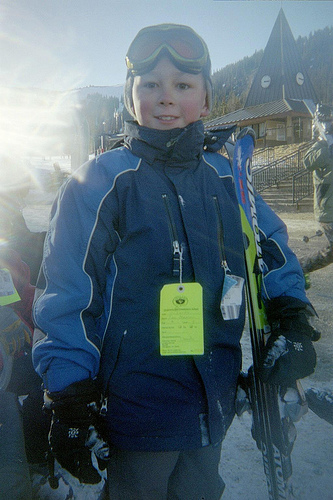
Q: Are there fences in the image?
A: No, there are no fences.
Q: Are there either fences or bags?
A: No, there are no fences or bags.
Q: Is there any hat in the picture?
A: Yes, there is a hat.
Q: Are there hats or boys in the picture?
A: Yes, there is a hat.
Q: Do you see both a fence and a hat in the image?
A: No, there is a hat but no fences.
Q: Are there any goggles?
A: Yes, there are goggles.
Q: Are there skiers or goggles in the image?
A: Yes, there are goggles.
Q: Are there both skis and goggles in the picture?
A: Yes, there are both goggles and a ski.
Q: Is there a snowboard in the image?
A: No, there are no snowboards.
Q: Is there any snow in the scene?
A: Yes, there is snow.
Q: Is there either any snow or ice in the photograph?
A: Yes, there is snow.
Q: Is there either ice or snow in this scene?
A: Yes, there is snow.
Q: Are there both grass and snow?
A: No, there is snow but no grass.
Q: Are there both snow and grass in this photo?
A: No, there is snow but no grass.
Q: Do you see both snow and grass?
A: No, there is snow but no grass.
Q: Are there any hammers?
A: No, there are no hammers.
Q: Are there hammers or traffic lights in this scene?
A: No, there are no hammers or traffic lights.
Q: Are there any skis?
A: Yes, there are skis.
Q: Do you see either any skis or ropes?
A: Yes, there are skis.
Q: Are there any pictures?
A: No, there are no pictures.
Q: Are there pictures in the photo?
A: No, there are no pictures.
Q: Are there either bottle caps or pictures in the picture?
A: No, there are no pictures or bottle caps.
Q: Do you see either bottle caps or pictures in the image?
A: No, there are no pictures or bottle caps.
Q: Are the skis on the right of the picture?
A: Yes, the skis are on the right of the image.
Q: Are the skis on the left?
A: No, the skis are on the right of the image.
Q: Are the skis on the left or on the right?
A: The skis are on the right of the image.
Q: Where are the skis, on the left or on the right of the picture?
A: The skis are on the right of the image.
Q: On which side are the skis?
A: The skis are on the right of the image.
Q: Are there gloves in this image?
A: Yes, there are gloves.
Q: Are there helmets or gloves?
A: Yes, there are gloves.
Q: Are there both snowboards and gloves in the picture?
A: No, there are gloves but no snowboards.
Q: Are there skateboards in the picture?
A: No, there are no skateboards.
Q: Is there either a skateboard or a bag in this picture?
A: No, there are no skateboards or bags.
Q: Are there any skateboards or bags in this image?
A: No, there are no skateboards or bags.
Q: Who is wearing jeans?
A: The boy is wearing jeans.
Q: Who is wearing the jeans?
A: The boy is wearing jeans.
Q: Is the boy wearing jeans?
A: Yes, the boy is wearing jeans.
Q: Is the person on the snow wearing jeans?
A: Yes, the boy is wearing jeans.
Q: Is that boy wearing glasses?
A: No, the boy is wearing jeans.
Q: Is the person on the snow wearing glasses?
A: No, the boy is wearing jeans.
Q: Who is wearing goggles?
A: The boy is wearing goggles.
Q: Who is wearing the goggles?
A: The boy is wearing goggles.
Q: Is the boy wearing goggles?
A: Yes, the boy is wearing goggles.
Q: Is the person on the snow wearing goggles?
A: Yes, the boy is wearing goggles.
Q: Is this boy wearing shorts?
A: No, the boy is wearing goggles.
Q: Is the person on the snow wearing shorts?
A: No, the boy is wearing goggles.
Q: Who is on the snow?
A: The boy is on the snow.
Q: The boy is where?
A: The boy is on the snow.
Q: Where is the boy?
A: The boy is on the snow.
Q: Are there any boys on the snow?
A: Yes, there is a boy on the snow.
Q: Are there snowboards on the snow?
A: No, there is a boy on the snow.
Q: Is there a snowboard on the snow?
A: No, there is a boy on the snow.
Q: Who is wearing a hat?
A: The boy is wearing a hat.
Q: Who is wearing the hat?
A: The boy is wearing a hat.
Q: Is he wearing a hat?
A: Yes, the boy is wearing a hat.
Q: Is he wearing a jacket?
A: No, the boy is wearing a hat.